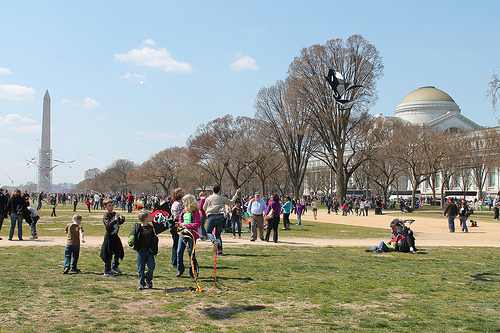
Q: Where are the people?
A: Field.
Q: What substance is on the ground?
A: Grass.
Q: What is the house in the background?
A: White house.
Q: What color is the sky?
A: Blue and white.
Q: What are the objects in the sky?
A: Kites.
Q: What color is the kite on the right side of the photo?
A: Black and white.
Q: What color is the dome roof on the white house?
A: Grey.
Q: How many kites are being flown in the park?
A: Three.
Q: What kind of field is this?
A: Park.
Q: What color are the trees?
A: Brown.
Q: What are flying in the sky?
A: Kites.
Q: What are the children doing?
A: Flying kites.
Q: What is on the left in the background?
A: Large tower.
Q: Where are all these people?
A: At a park.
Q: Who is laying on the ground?
A: Woman and baby.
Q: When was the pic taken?
A: During the day.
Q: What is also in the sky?
A: White clouds.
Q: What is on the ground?
A: Green grass.